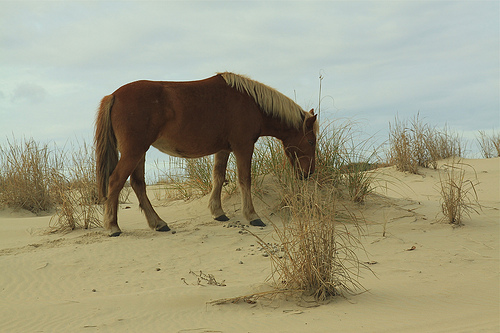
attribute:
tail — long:
[84, 67, 322, 239]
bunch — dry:
[248, 152, 350, 307]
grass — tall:
[243, 128, 349, 300]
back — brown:
[117, 71, 270, 101]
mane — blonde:
[218, 70, 320, 136]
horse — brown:
[81, 68, 322, 255]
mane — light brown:
[215, 67, 323, 134]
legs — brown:
[105, 145, 265, 238]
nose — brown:
[302, 167, 313, 182]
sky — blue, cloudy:
[2, 3, 497, 185]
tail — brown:
[74, 84, 126, 198]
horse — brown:
[90, 69, 314, 222]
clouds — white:
[22, 14, 124, 69]